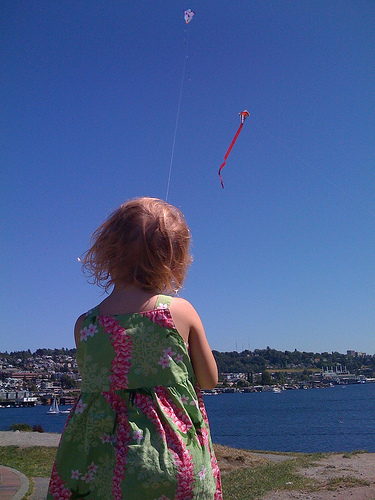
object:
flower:
[158, 353, 172, 369]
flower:
[162, 345, 176, 357]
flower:
[174, 353, 184, 364]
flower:
[180, 393, 189, 405]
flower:
[79, 323, 98, 342]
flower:
[84, 460, 99, 484]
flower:
[99, 432, 109, 444]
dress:
[45, 294, 222, 500]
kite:
[183, 9, 194, 24]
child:
[45, 197, 221, 499]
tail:
[218, 123, 244, 189]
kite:
[238, 109, 250, 123]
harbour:
[0, 394, 51, 407]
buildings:
[323, 363, 354, 383]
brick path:
[3, 466, 29, 499]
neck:
[112, 274, 151, 297]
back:
[126, 347, 175, 381]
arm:
[188, 320, 219, 389]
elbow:
[202, 379, 218, 390]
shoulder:
[154, 294, 192, 314]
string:
[174, 113, 178, 138]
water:
[244, 389, 372, 449]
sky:
[0, 2, 375, 210]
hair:
[79, 197, 194, 295]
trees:
[218, 346, 355, 372]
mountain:
[213, 348, 323, 376]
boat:
[47, 397, 72, 415]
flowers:
[96, 308, 133, 500]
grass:
[224, 471, 283, 490]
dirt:
[324, 468, 369, 490]